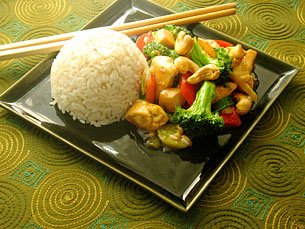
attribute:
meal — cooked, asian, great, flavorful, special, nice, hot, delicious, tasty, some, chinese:
[50, 24, 259, 152]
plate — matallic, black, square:
[0, 2, 299, 212]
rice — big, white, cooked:
[51, 27, 148, 128]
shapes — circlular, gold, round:
[30, 169, 109, 228]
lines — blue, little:
[233, 188, 273, 220]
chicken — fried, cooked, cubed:
[125, 100, 167, 132]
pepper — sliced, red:
[221, 111, 241, 128]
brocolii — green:
[174, 82, 224, 138]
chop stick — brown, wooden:
[0, 2, 237, 58]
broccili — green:
[174, 80, 222, 135]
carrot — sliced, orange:
[145, 72, 157, 103]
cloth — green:
[0, 1, 304, 228]